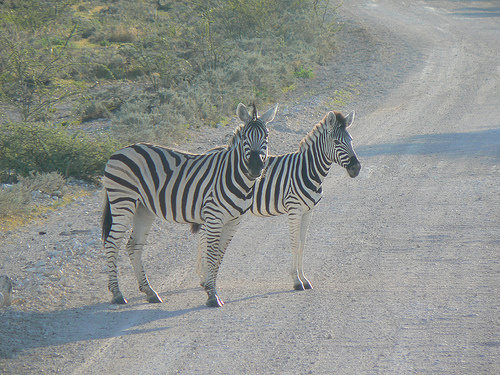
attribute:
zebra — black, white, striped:
[104, 106, 274, 312]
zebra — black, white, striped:
[274, 108, 371, 271]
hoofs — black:
[203, 278, 231, 310]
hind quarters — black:
[88, 146, 135, 252]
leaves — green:
[27, 43, 129, 128]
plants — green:
[151, 6, 263, 80]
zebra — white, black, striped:
[96, 102, 270, 320]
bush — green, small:
[1, 116, 121, 190]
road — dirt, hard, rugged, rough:
[126, 7, 495, 370]